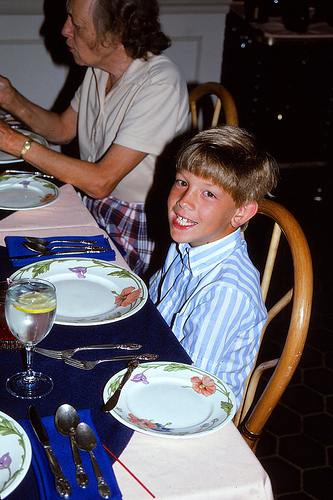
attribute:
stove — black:
[235, 29, 332, 173]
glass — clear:
[6, 277, 60, 351]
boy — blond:
[164, 125, 280, 245]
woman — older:
[56, 19, 208, 173]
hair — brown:
[97, 6, 227, 61]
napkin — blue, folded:
[17, 407, 122, 497]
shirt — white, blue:
[148, 227, 269, 418]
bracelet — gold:
[18, 138, 33, 157]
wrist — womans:
[4, 88, 22, 117]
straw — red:
[98, 440, 159, 499]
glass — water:
[1, 276, 68, 400]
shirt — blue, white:
[146, 227, 266, 404]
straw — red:
[96, 441, 155, 499]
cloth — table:
[176, 293, 258, 369]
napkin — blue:
[28, 397, 105, 490]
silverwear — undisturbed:
[15, 249, 107, 260]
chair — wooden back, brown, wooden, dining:
[246, 196, 314, 446]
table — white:
[0, 165, 152, 336]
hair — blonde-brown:
[174, 121, 283, 211]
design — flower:
[109, 348, 248, 453]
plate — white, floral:
[5, 255, 149, 326]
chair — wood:
[208, 194, 311, 453]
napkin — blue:
[4, 229, 121, 273]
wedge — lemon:
[14, 292, 56, 314]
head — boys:
[164, 125, 271, 243]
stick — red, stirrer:
[98, 439, 164, 497]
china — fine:
[101, 361, 239, 438]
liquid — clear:
[3, 281, 56, 344]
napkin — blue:
[6, 233, 116, 269]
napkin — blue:
[3, 234, 118, 263]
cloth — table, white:
[3, 118, 280, 497]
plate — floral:
[0, 173, 59, 209]